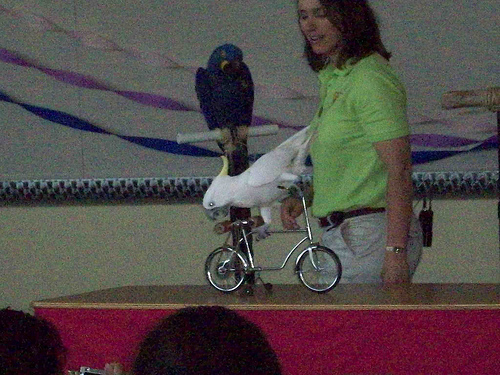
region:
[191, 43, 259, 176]
Blue parrot looking down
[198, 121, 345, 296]
A bird riding a bicycle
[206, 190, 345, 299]
A small toy bicycle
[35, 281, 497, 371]
A red and brown wooden stand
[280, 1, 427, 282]
A woman in a green polo shirt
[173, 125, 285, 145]
The bar on a bird's perch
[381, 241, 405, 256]
A small watch on a woman's wrist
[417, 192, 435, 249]
Walkie Talkie on a woman's belt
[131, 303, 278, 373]
The top of a person's head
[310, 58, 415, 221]
A green polo shirt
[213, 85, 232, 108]
the bird is blue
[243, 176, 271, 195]
the bird is white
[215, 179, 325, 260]
the bird is on the bike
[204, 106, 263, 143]
the bird is sitting on the perch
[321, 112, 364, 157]
the shirt is lime green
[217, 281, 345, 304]
the bike is on the table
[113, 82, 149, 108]
the streamer is purple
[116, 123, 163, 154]
the streamer is blue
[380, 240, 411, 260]
she is wearing a watch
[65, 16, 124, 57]
twist of colored ribbon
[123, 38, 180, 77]
twist of colored ribbon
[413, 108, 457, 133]
twist of colored ribbon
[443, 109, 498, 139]
twist of colored ribbon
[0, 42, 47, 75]
twist of colored ribbon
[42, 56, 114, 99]
twist of colored ribbon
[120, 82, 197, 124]
twist of colored ribbon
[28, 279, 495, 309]
a wood topped table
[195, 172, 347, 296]
a tiny silver bicycle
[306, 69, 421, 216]
a neon green polo shirt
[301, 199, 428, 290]
off white slacks with brown belt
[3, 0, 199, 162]
streamers of pink, purple and dark blue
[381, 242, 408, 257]
a wrist watch with a white band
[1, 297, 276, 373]
heads of spectators in foreground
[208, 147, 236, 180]
the crest of the cockatoo is yellow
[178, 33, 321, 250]
a blue bird and a white bird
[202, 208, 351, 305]
a small bike for birds to do tricks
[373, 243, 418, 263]
a silver wrist watch on wrist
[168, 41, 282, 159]
a blue bird on a perch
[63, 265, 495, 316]
a wooden table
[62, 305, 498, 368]
a pink table skirt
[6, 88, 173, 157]
a blue streamer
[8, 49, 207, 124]
a purple streamer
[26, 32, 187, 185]
streamers hung up on the wall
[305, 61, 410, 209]
the shirt of a woman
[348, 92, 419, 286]
the left arm of a woman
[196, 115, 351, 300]
A white parakeet riding a tiny bicycle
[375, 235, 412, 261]
A watch around a wrist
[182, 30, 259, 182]
A blue parakeet sitting on a stick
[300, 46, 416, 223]
A green short sleeved shirt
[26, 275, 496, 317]
A brown wooden table surface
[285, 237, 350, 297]
A small round bicycle wheel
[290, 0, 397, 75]
The woman has brown hair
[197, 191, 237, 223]
The beak of a bird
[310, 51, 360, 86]
Green collar of a shirt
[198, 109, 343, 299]
bird on a bike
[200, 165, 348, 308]
a small silver bike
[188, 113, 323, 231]
the bird is white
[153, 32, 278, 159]
bird on a stande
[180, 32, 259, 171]
the bird is blue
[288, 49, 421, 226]
woman wearing a green shirt